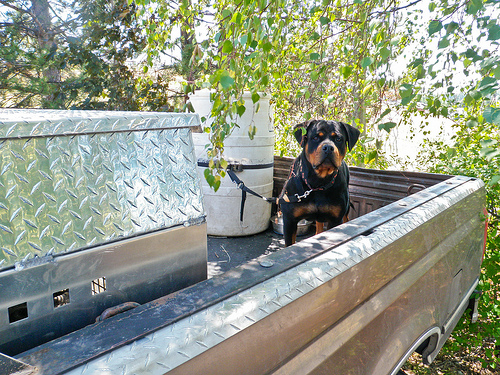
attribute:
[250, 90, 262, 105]
leaf — yellow, green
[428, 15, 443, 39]
leaf — yellow, green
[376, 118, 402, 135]
leaf — yellow, green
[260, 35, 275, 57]
leaf — yellow, green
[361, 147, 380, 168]
leaf — yellow, green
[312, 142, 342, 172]
nose — small, black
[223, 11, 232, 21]
leaves — green , yellow 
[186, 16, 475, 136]
leaves — green and yellow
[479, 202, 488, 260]
rear taillights — side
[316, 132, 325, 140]
spot — brown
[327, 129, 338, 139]
spot — brown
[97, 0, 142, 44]
leaves — green, yellow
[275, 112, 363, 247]
dog — imposing, black, brown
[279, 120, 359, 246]
dog — large, black, brown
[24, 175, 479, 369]
metal strip — black, rusted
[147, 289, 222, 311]
rusted spots — orange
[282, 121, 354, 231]
dog — black, brown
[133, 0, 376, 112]
leaves — green, yellow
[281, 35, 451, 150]
leaves — green, yellow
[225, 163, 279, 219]
leash — stretched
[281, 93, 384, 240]
dog — large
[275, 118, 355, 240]
dog — black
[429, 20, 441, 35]
leaf — green, yellow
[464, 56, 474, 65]
leaf — green, yellow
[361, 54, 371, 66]
leaf — green, yellow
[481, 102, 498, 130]
leaf — green, yellow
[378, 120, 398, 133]
leaf — green, yellow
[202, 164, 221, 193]
leaves — yellow, green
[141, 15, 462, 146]
branch — colored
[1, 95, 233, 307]
tool box — silver